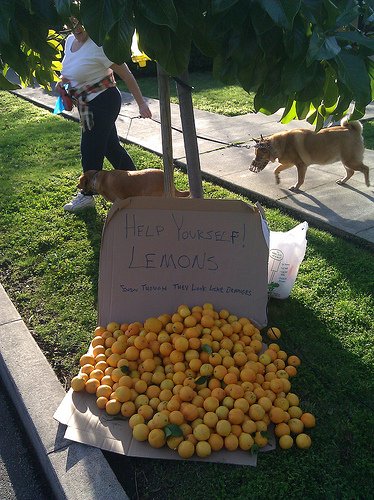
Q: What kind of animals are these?
A: Dogs.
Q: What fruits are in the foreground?
A: Lemons.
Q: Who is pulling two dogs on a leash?
A: A woman.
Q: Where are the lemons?
A: On the ground.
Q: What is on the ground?
A: Lemons.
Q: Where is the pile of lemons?
A: On the ground.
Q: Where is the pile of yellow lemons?
A: On the ground.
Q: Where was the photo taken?
A: Next to a sidewalk.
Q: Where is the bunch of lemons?
A: Under a cardboard sign.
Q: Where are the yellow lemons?
A: Next to the sidewalk.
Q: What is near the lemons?
A: A cardboard box.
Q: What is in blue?
A: The writing.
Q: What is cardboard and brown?
A: The box.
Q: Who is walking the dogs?
A: The woman.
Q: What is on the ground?
A: Lemons.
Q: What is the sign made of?
A: Cardboard.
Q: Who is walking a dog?
A: A woman.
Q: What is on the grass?
A: Lemons.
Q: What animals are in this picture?
A: Dogs.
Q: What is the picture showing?
A: Free lemons.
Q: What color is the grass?
A: Green.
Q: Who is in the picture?
A: A women.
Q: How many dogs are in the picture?
A: Two.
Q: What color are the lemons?
A: Yellos.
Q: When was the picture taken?
A: During the day.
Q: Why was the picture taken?
A: To capture the lemons.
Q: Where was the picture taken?
A: Along a sidewalk.